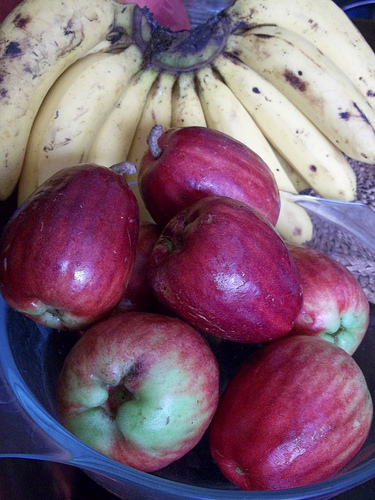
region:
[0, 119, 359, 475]
bowl of fruit in front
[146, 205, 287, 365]
red piece of fruit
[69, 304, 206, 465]
red and green piece of fruit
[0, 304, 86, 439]
blue holder for fruit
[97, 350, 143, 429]
small hole in fruit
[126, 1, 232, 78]
brown parts of banana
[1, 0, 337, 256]
group of yellow bananas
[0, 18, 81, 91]
brown spots on side of banan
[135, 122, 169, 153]
brown stem of apple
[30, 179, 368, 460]
bowl of red and green apples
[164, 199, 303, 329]
a sweet juicy red apple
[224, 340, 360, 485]
a sweet juicy red apple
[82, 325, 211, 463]
a sweet juicy red apple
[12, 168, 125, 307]
a sweet juicy red apple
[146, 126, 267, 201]
a sweet juicy red apple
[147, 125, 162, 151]
a thick brown stem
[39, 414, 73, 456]
the edge of a glass bowl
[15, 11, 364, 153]
a bunch of yellow bananas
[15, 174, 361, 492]
a bowl of red apples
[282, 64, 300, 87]
a brown spot on a banana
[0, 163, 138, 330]
shiny ripe red apple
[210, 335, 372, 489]
shiny ripe red apple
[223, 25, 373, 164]
yellow banana with brown spots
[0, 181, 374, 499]
blue translucent fruit bowl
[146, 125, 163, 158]
short gnarled apple stem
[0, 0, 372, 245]
bunch of yellow bananas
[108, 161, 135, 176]
short woody apple stem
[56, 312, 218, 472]
red apple with green top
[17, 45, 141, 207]
yellow banana with brown spots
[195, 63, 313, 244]
yellow banana with brown spots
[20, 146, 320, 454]
bowl of colored fruit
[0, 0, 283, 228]
group of bananas together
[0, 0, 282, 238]
bushel of bananas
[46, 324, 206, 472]
red and green apple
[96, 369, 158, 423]
small hole in end of apple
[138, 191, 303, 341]
red apple in middle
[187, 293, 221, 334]
small marks on side of apple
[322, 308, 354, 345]
green marks on bottom of apple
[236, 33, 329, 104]
black marks on banana side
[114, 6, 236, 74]
brown meeting point of bananas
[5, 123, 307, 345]
oval red fruit crossed with purple lines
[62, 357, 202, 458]
dark end of green and red fruit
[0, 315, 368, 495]
blue lines along edge of bowl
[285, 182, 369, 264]
triangular glass handle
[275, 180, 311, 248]
tip of banana through side of glass bowl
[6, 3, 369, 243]
bananas fanning out from center stem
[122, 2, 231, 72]
ring around edge of bananas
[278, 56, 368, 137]
dark spots and bruises on bananas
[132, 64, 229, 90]
dark spaces between bananas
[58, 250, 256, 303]
light reflecting off fruit